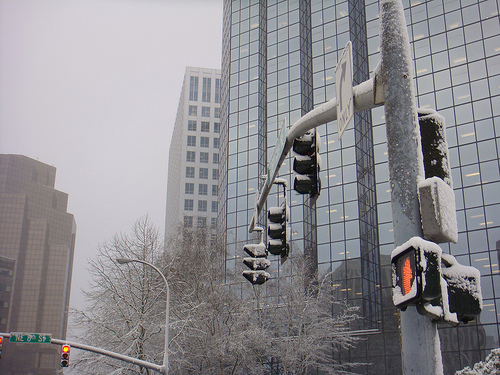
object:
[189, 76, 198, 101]
window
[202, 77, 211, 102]
window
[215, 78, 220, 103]
window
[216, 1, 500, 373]
building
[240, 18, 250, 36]
window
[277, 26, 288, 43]
window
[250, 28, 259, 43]
window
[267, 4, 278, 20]
window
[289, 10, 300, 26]
window